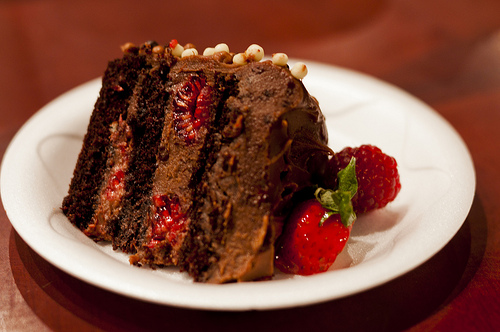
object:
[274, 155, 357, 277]
strawberry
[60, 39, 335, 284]
cake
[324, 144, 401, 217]
raspberry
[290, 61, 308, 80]
nuts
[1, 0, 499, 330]
table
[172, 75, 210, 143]
sauce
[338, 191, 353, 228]
leaf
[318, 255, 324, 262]
seeds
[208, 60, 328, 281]
icing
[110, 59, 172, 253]
chocolate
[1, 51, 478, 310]
dish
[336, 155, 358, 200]
leaves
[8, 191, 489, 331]
shadow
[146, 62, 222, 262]
layers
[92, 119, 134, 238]
frosting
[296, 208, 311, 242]
reflection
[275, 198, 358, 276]
skin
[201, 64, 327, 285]
frosting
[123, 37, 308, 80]
decoration